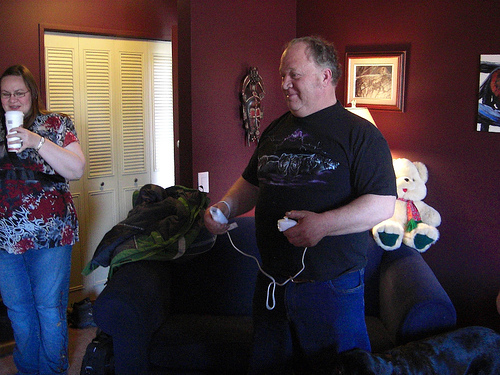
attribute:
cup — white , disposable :
[6, 107, 25, 151]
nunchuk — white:
[276, 215, 296, 232]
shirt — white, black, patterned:
[4, 114, 76, 240]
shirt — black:
[237, 100, 397, 281]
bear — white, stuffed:
[371, 155, 441, 253]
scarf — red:
[396, 196, 421, 234]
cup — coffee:
[4, 110, 24, 152]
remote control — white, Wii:
[209, 204, 229, 226]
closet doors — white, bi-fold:
[78, 35, 158, 305]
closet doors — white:
[42, 31, 177, 313]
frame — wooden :
[342, 47, 406, 113]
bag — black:
[76, 324, 107, 373]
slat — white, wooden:
[121, 160, 157, 168]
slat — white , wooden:
[82, 149, 112, 162]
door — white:
[82, 47, 114, 247]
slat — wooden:
[86, 98, 110, 108]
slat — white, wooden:
[122, 78, 145, 88]